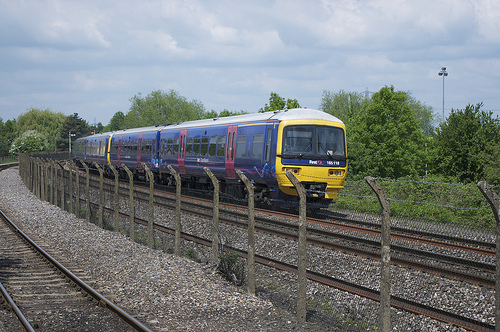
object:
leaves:
[438, 140, 450, 150]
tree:
[356, 84, 432, 178]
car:
[158, 107, 348, 217]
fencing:
[19, 152, 500, 332]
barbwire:
[375, 177, 479, 217]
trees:
[15, 107, 67, 157]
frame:
[355, 82, 377, 99]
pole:
[441, 76, 444, 122]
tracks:
[5, 219, 147, 332]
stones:
[153, 270, 201, 293]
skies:
[0, 52, 500, 126]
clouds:
[35, 72, 107, 109]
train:
[72, 108, 349, 219]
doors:
[225, 125, 238, 180]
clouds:
[37, 18, 116, 57]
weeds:
[215, 233, 247, 285]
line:
[17, 145, 499, 332]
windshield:
[281, 124, 346, 166]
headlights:
[282, 166, 301, 175]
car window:
[236, 134, 246, 160]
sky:
[85, 20, 341, 110]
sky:
[0, 1, 500, 126]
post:
[283, 169, 307, 319]